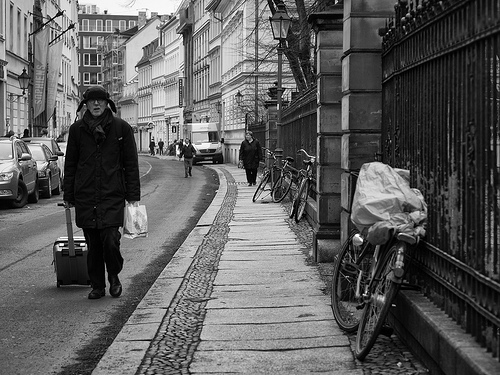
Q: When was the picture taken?
A: Daytime.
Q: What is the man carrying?
A: Suitcase.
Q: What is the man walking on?
A: The street.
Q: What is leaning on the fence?
A: A bike.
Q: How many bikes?
A: 4.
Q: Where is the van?
A: On the sidewalk.